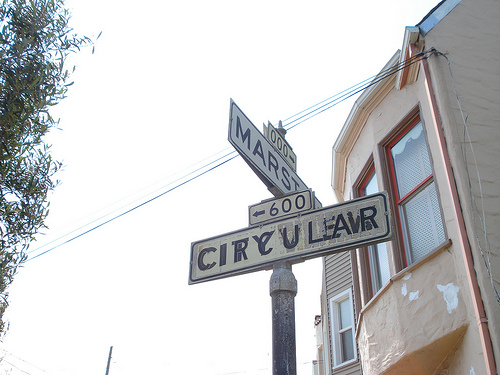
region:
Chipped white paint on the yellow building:
[440, 283, 468, 319]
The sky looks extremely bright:
[118, 54, 185, 124]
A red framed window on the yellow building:
[380, 118, 450, 257]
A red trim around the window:
[382, 145, 402, 206]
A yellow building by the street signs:
[328, 32, 491, 364]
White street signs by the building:
[178, 118, 387, 270]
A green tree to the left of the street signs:
[0, 5, 55, 350]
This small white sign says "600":
[247, 188, 319, 226]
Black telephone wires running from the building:
[322, 58, 429, 105]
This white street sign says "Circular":
[200, 220, 394, 279]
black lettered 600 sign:
[241, 190, 321, 222]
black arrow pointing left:
[246, 201, 270, 222]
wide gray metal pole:
[268, 267, 298, 374]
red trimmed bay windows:
[329, 102, 464, 372]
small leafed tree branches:
[9, 8, 111, 203]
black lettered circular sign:
[180, 186, 393, 285]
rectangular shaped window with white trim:
[320, 283, 362, 373]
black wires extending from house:
[277, 30, 450, 130]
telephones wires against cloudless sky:
[76, 156, 226, 221]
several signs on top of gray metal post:
[183, 85, 398, 371]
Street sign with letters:
[176, 205, 418, 278]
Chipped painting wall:
[366, 263, 471, 341]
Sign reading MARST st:
[216, 103, 318, 197]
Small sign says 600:
[228, 197, 357, 221]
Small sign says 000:
[267, 120, 314, 167]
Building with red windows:
[363, 110, 485, 270]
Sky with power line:
[101, 108, 225, 319]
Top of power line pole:
[81, 337, 143, 373]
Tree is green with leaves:
[8, 75, 115, 289]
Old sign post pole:
[252, 260, 319, 365]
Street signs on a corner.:
[182, 101, 397, 288]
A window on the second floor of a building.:
[375, 103, 453, 271]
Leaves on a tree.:
[0, 0, 72, 342]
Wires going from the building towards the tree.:
[22, 43, 439, 268]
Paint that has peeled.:
[431, 274, 464, 321]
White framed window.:
[323, 289, 361, 370]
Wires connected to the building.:
[422, 42, 447, 68]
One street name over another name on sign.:
[190, 196, 408, 282]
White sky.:
[115, 27, 197, 142]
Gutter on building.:
[399, 22, 419, 94]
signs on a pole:
[193, 111, 392, 293]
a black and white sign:
[190, 191, 386, 293]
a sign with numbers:
[246, 196, 317, 224]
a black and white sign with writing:
[201, 196, 393, 285]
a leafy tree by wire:
[4, 1, 89, 327]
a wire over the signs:
[29, 45, 450, 282]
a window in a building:
[336, 122, 438, 317]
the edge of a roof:
[361, 11, 443, 116]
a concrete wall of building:
[446, 4, 498, 148]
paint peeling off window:
[396, 265, 461, 338]